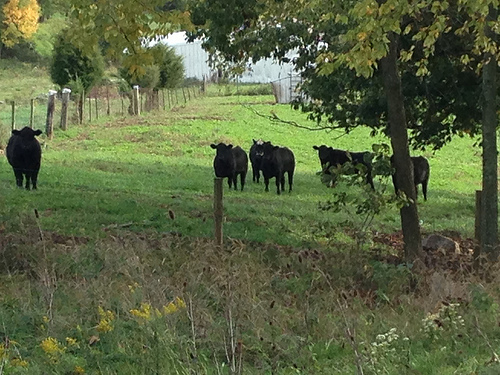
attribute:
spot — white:
[256, 140, 262, 145]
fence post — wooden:
[212, 177, 221, 252]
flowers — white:
[365, 299, 468, 359]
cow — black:
[207, 139, 249, 192]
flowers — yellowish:
[129, 295, 186, 319]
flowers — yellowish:
[92, 305, 115, 331]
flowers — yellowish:
[38, 335, 81, 359]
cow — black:
[2, 117, 48, 194]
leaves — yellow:
[73, 232, 274, 326]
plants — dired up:
[195, 232, 252, 370]